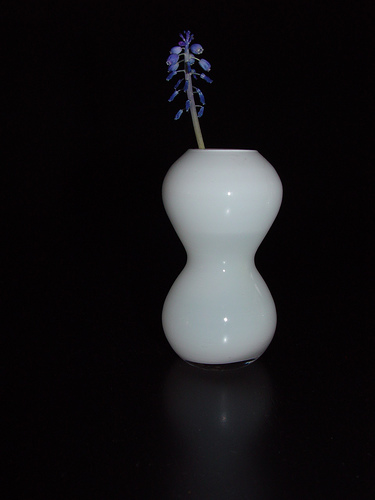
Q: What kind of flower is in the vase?
A: Lilac.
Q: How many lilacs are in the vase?
A: One.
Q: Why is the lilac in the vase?
A: To keep it fresh.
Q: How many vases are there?
A: One.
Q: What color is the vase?
A: White.